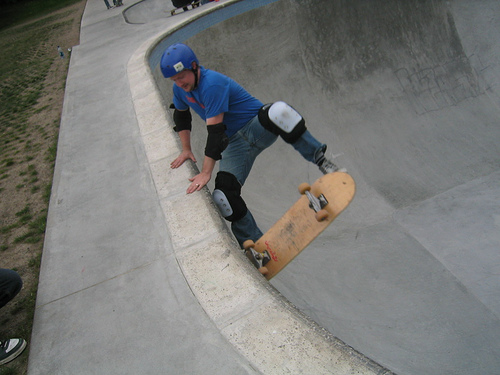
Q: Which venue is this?
A: This is a pavement.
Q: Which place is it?
A: It is a pavement.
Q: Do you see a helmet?
A: Yes, there is a helmet.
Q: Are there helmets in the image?
A: Yes, there is a helmet.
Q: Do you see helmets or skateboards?
A: Yes, there is a helmet.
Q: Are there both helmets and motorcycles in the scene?
A: No, there is a helmet but no motorcycles.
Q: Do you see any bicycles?
A: No, there are no bicycles.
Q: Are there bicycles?
A: No, there are no bicycles.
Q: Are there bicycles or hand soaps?
A: No, there are no bicycles or hand soaps.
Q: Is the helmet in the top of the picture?
A: Yes, the helmet is in the top of the image.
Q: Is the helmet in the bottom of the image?
A: No, the helmet is in the top of the image.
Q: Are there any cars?
A: No, there are no cars.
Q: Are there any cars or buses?
A: No, there are no cars or buses.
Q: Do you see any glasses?
A: No, there are no glasses.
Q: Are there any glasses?
A: No, there are no glasses.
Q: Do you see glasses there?
A: No, there are no glasses.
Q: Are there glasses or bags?
A: No, there are no glasses or bags.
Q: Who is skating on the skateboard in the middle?
A: The man is skating on the skateboard.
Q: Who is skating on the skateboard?
A: The man is skating on the skateboard.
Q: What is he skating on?
A: The man is skating on the skateboard.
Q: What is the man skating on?
A: The man is skating on the skateboard.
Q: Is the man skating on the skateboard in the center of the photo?
A: Yes, the man is skating on the skateboard.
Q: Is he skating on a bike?
A: No, the man is skating on the skateboard.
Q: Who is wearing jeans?
A: The man is wearing jeans.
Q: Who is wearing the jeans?
A: The man is wearing jeans.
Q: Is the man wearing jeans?
A: Yes, the man is wearing jeans.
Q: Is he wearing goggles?
A: No, the man is wearing jeans.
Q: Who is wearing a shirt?
A: The man is wearing a shirt.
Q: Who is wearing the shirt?
A: The man is wearing a shirt.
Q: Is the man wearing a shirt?
A: Yes, the man is wearing a shirt.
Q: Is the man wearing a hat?
A: No, the man is wearing a shirt.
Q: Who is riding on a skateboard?
A: The man is riding on a skateboard.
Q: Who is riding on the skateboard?
A: The man is riding on a skateboard.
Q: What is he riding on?
A: The man is riding on a skateboard.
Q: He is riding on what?
A: The man is riding on a skateboard.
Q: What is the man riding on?
A: The man is riding on a skateboard.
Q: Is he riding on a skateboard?
A: Yes, the man is riding on a skateboard.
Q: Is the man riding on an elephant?
A: No, the man is riding on a skateboard.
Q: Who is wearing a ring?
A: The man is wearing a ring.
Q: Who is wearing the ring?
A: The man is wearing a ring.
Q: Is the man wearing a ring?
A: Yes, the man is wearing a ring.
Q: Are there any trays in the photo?
A: No, there are no trays.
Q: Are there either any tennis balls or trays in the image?
A: No, there are no trays or tennis balls.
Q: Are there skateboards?
A: Yes, there is a skateboard.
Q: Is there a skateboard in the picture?
A: Yes, there is a skateboard.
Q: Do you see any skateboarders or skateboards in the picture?
A: Yes, there is a skateboard.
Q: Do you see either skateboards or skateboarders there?
A: Yes, there is a skateboard.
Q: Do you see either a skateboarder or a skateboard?
A: Yes, there is a skateboard.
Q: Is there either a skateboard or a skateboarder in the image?
A: Yes, there is a skateboard.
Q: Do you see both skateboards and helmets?
A: Yes, there are both a skateboard and a helmet.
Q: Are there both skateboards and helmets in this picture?
A: Yes, there are both a skateboard and a helmet.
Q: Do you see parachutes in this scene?
A: No, there are no parachutes.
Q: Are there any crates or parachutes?
A: No, there are no parachutes or crates.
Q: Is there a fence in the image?
A: No, there are no fences.